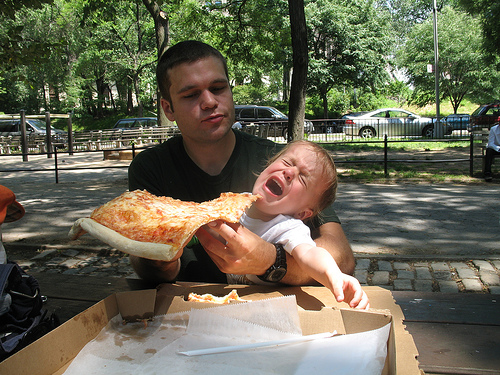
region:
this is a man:
[138, 26, 270, 185]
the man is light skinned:
[168, 95, 203, 134]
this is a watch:
[268, 232, 298, 289]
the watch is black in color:
[269, 247, 285, 272]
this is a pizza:
[102, 190, 177, 250]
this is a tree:
[313, 7, 393, 87]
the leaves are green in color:
[342, 11, 381, 63]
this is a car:
[343, 104, 428, 153]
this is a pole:
[432, 5, 449, 127]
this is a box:
[108, 285, 243, 371]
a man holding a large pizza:
[68, 170, 261, 262]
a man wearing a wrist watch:
[250, 242, 290, 288]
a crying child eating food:
[120, 138, 369, 313]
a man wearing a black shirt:
[118, 123, 343, 290]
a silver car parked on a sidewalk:
[342, 108, 454, 141]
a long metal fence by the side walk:
[3, 114, 498, 155]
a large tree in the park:
[258, 0, 340, 195]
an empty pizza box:
[0, 265, 427, 373]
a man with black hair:
[155, 35, 229, 116]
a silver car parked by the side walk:
[0, 118, 77, 153]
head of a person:
[248, 131, 351, 213]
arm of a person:
[295, 236, 370, 296]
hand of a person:
[328, 271, 374, 313]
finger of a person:
[336, 282, 374, 309]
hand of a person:
[209, 218, 289, 287]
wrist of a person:
[268, 232, 288, 284]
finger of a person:
[202, 219, 250, 270]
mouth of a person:
[260, 171, 292, 201]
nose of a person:
[278, 165, 305, 182]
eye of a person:
[282, 151, 305, 170]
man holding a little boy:
[128, 40, 370, 310]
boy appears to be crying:
[256, 140, 323, 208]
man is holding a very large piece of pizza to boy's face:
[68, 40, 338, 262]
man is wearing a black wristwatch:
[257, 242, 287, 287]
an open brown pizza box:
[2, 279, 423, 374]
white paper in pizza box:
[64, 294, 390, 374]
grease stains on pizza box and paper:
[74, 304, 185, 364]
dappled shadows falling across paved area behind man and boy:
[1, 40, 498, 374]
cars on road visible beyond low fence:
[1, 102, 498, 154]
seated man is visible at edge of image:
[478, 114, 499, 177]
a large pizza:
[106, 201, 178, 233]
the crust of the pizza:
[136, 240, 159, 257]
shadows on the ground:
[385, 184, 456, 225]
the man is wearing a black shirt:
[151, 160, 183, 182]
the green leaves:
[66, 68, 88, 102]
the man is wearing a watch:
[266, 263, 285, 282]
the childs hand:
[328, 274, 377, 311]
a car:
[356, 108, 416, 122]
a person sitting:
[483, 124, 498, 162]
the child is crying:
[256, 144, 330, 213]